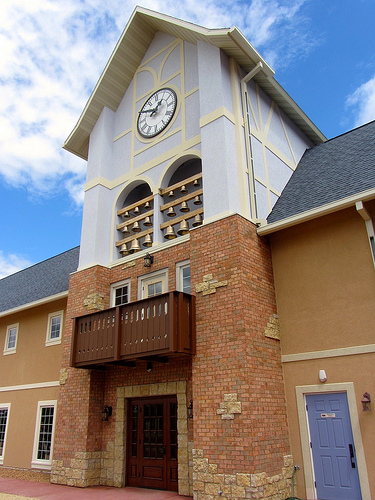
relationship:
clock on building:
[136, 85, 187, 140] [0, 6, 374, 498]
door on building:
[129, 386, 183, 485] [0, 6, 374, 498]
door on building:
[303, 390, 361, 499] [0, 6, 374, 498]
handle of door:
[347, 443, 355, 472] [303, 390, 361, 499]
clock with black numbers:
[133, 87, 177, 138] [138, 94, 174, 131]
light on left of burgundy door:
[99, 398, 122, 423] [124, 400, 177, 488]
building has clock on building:
[0, 6, 374, 498] [127, 79, 188, 143]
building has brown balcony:
[0, 6, 374, 498] [76, 292, 199, 366]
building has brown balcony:
[0, 6, 374, 498] [64, 288, 206, 371]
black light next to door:
[100, 403, 113, 422] [122, 393, 177, 490]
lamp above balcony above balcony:
[134, 251, 160, 270] [68, 290, 197, 369]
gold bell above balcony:
[140, 230, 162, 248] [68, 290, 197, 369]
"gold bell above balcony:
[141, 213, 158, 229] [68, 290, 197, 369]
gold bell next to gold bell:
[179, 201, 193, 216] [140, 230, 162, 248]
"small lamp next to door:
[359, 387, 370, 412] [303, 390, 361, 499]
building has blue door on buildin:
[0, 6, 374, 498] [306, 379, 355, 478]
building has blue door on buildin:
[0, 6, 374, 498] [292, 380, 368, 498]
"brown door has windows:
[125, 399, 177, 494] [129, 402, 177, 460]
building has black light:
[0, 6, 374, 498] [96, 403, 110, 426]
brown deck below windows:
[81, 324, 138, 360] [112, 267, 193, 307]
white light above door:
[313, 367, 333, 382] [303, 390, 361, 499]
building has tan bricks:
[0, 6, 374, 498] [211, 473, 262, 496]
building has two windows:
[0, 6, 374, 498] [1, 391, 61, 467]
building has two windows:
[0, 6, 374, 498] [1, 313, 66, 353]